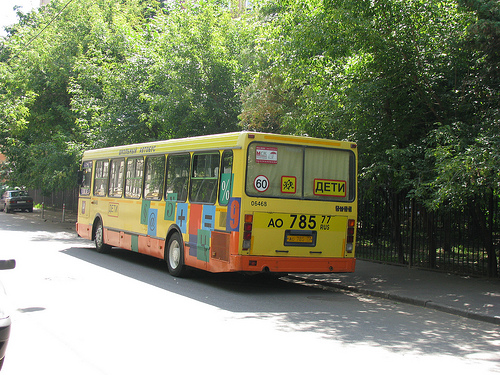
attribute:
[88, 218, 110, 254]
tire — driver side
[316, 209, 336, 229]
number — 77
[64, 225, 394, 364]
shadow — rectangular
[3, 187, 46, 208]
car — parked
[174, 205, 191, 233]
sign — black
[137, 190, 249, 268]
signs — colored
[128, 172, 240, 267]
signs — green, red, blue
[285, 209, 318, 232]
number — 785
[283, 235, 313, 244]
plate — license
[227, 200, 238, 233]
9 — red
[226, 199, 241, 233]
background — blue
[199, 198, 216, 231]
background — blue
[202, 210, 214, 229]
equal sign — black